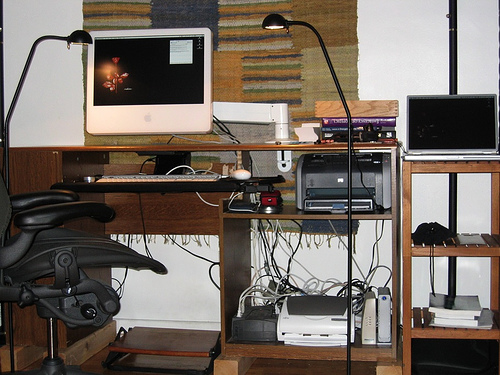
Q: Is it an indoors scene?
A: Yes, it is indoors.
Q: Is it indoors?
A: Yes, it is indoors.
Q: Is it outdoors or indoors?
A: It is indoors.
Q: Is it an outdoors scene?
A: No, it is indoors.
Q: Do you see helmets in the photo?
A: No, there are no helmets.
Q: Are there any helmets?
A: No, there are no helmets.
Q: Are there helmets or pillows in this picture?
A: No, there are no helmets or pillows.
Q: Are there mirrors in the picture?
A: No, there are no mirrors.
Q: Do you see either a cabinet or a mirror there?
A: No, there are no mirrors or cabinets.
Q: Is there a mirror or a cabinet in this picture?
A: No, there are no mirrors or cabinets.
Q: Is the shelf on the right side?
A: Yes, the shelf is on the right of the image.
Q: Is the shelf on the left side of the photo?
A: No, the shelf is on the right of the image.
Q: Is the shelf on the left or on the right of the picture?
A: The shelf is on the right of the image.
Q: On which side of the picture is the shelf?
A: The shelf is on the right of the image.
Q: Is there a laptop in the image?
A: Yes, there is a laptop.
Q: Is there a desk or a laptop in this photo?
A: Yes, there is a laptop.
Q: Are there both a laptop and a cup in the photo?
A: No, there is a laptop but no cups.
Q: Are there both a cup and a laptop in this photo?
A: No, there is a laptop but no cups.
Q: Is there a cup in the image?
A: No, there are no cups.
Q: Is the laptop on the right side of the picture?
A: Yes, the laptop is on the right of the image.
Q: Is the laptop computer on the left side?
A: No, the laptop computer is on the right of the image.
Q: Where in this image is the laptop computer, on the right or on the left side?
A: The laptop computer is on the right of the image.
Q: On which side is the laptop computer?
A: The laptop computer is on the right of the image.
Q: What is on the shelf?
A: The laptop computer is on the shelf.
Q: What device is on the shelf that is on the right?
A: The device is a laptop.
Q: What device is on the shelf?
A: The device is a laptop.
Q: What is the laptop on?
A: The laptop is on the shelf.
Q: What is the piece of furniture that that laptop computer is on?
A: The piece of furniture is a shelf.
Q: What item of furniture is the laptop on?
A: The laptop computer is on the shelf.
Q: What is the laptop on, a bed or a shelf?
A: The laptop is on a shelf.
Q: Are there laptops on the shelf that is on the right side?
A: Yes, there is a laptop on the shelf.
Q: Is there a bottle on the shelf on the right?
A: No, there is a laptop on the shelf.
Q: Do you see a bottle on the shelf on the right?
A: No, there is a laptop on the shelf.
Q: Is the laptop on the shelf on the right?
A: Yes, the laptop is on the shelf.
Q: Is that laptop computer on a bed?
A: No, the laptop computer is on the shelf.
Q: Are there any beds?
A: No, there are no beds.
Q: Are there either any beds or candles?
A: No, there are no beds or candles.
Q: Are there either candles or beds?
A: No, there are no beds or candles.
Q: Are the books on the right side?
A: Yes, the books are on the right of the image.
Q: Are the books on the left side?
A: No, the books are on the right of the image.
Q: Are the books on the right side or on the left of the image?
A: The books are on the right of the image.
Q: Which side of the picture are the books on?
A: The books are on the right of the image.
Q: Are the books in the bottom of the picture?
A: Yes, the books are in the bottom of the image.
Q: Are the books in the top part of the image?
A: No, the books are in the bottom of the image.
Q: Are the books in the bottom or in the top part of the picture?
A: The books are in the bottom of the image.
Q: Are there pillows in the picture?
A: No, there are no pillows.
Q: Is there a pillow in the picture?
A: No, there are no pillows.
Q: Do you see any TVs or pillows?
A: No, there are no pillows or tvs.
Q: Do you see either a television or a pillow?
A: No, there are no pillows or televisions.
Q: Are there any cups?
A: No, there are no cups.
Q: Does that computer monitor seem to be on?
A: Yes, the computer monitor is on.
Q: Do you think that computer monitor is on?
A: Yes, the computer monitor is on.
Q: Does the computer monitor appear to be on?
A: Yes, the computer monitor is on.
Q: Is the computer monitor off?
A: No, the computer monitor is on.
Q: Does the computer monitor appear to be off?
A: No, the computer monitor is on.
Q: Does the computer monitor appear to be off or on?
A: The computer monitor is on.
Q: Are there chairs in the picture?
A: Yes, there is a chair.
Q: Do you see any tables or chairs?
A: Yes, there is a chair.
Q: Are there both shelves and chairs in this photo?
A: Yes, there are both a chair and a shelf.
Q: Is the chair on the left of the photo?
A: Yes, the chair is on the left of the image.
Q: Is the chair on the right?
A: No, the chair is on the left of the image.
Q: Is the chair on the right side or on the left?
A: The chair is on the left of the image.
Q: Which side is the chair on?
A: The chair is on the left of the image.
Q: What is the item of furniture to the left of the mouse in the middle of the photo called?
A: The piece of furniture is a chair.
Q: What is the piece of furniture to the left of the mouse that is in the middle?
A: The piece of furniture is a chair.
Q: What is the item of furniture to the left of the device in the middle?
A: The piece of furniture is a chair.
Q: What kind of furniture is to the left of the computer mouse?
A: The piece of furniture is a chair.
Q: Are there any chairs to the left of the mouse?
A: Yes, there is a chair to the left of the mouse.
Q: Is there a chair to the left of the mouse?
A: Yes, there is a chair to the left of the mouse.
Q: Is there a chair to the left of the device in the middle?
A: Yes, there is a chair to the left of the mouse.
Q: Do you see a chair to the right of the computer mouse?
A: No, the chair is to the left of the computer mouse.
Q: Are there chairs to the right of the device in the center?
A: No, the chair is to the left of the computer mouse.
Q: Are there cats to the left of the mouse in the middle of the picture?
A: No, there is a chair to the left of the computer mouse.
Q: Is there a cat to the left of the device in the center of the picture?
A: No, there is a chair to the left of the computer mouse.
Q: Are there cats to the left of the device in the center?
A: No, there is a chair to the left of the computer mouse.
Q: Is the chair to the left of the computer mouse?
A: Yes, the chair is to the left of the computer mouse.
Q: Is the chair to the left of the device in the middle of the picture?
A: Yes, the chair is to the left of the computer mouse.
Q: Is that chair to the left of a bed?
A: No, the chair is to the left of the computer mouse.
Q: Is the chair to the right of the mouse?
A: No, the chair is to the left of the mouse.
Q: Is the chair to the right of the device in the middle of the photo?
A: No, the chair is to the left of the mouse.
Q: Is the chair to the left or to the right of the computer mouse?
A: The chair is to the left of the computer mouse.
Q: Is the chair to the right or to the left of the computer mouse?
A: The chair is to the left of the computer mouse.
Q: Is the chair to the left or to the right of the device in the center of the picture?
A: The chair is to the left of the computer mouse.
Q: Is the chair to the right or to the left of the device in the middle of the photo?
A: The chair is to the left of the computer mouse.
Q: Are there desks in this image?
A: Yes, there is a desk.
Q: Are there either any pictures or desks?
A: Yes, there is a desk.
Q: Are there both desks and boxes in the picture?
A: No, there is a desk but no boxes.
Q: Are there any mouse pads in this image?
A: No, there are no mouse pads.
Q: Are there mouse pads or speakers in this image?
A: No, there are no mouse pads or speakers.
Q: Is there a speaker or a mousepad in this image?
A: No, there are no mouse pads or speakers.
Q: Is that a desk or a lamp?
A: That is a desk.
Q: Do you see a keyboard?
A: Yes, there is a keyboard.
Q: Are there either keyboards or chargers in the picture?
A: Yes, there is a keyboard.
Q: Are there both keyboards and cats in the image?
A: No, there is a keyboard but no cats.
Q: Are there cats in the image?
A: No, there are no cats.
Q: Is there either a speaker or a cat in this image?
A: No, there are no cats or speakers.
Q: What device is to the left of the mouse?
A: The device is a keyboard.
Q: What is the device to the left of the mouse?
A: The device is a keyboard.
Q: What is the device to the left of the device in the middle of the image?
A: The device is a keyboard.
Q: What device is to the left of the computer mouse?
A: The device is a keyboard.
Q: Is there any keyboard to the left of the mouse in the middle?
A: Yes, there is a keyboard to the left of the mouse.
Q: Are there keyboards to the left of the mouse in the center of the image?
A: Yes, there is a keyboard to the left of the mouse.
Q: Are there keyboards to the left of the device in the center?
A: Yes, there is a keyboard to the left of the mouse.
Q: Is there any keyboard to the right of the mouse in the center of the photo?
A: No, the keyboard is to the left of the mouse.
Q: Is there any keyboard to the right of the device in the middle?
A: No, the keyboard is to the left of the mouse.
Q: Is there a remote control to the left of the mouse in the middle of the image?
A: No, there is a keyboard to the left of the computer mouse.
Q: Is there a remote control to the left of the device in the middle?
A: No, there is a keyboard to the left of the computer mouse.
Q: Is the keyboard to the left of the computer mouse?
A: Yes, the keyboard is to the left of the computer mouse.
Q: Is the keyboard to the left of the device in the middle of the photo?
A: Yes, the keyboard is to the left of the computer mouse.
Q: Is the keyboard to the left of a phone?
A: No, the keyboard is to the left of the computer mouse.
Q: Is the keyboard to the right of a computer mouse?
A: No, the keyboard is to the left of a computer mouse.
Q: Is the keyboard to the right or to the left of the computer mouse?
A: The keyboard is to the left of the computer mouse.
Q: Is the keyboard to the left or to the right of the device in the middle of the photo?
A: The keyboard is to the left of the computer mouse.